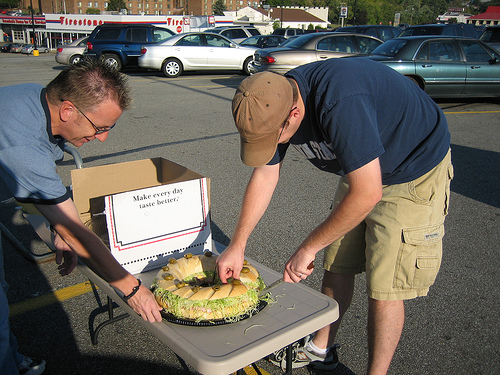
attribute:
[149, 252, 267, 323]
sandwich — circle shaped, large, wheel shaped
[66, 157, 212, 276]
box — cardboard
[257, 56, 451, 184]
t-shirt — blue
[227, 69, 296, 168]
cap — brown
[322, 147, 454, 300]
shorts — tan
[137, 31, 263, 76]
car — white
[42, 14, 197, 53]
store — firestone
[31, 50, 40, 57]
base — yellow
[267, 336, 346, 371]
sneakers — grey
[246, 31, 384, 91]
car — silver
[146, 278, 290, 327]
tray — black